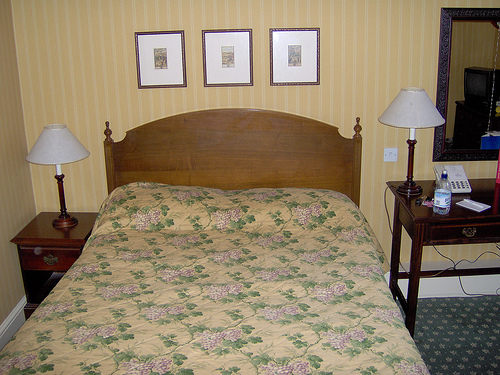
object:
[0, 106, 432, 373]
bed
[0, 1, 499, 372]
bedroom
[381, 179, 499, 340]
wood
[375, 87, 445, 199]
lamp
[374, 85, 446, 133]
shade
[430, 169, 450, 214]
bottle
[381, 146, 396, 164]
light switch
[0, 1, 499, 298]
wall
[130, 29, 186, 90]
picture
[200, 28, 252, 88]
picture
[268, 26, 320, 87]
picture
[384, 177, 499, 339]
table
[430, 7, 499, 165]
mirror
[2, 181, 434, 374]
cover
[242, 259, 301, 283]
pink flowers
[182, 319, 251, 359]
pink flower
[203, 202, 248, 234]
pink flower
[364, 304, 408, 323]
pink flower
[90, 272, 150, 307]
pink flower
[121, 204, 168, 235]
pink flower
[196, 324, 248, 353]
flower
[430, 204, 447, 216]
water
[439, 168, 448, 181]
sport top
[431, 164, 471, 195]
telephone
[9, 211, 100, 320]
night stand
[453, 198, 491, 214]
paper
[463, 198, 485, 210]
pen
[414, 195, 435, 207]
keys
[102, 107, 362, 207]
headboard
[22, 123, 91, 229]
lamp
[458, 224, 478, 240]
handle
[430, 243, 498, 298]
cord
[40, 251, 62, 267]
handle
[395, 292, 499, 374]
floor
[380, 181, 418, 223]
edge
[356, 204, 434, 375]
edge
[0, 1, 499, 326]
wallpaper